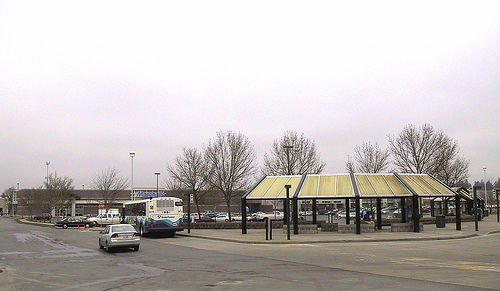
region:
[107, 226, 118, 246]
a tail light on a car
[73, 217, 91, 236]
orange cones in the street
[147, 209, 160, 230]
lights on the back of the bus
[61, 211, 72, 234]
a tire on the car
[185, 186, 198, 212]
a sign on a pole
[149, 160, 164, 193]
a light beside the street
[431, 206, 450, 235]
a garbage can on the sidewalk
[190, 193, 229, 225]
cars parked in the parking lot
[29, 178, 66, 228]
trees planted next to the building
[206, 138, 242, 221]
a tree with no leaves on it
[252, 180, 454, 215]
gold roof on right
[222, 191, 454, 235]
black poles are supporting roof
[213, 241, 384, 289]
sidewalk is dark grey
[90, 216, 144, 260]
silver car on road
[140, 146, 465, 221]
bare trees behind building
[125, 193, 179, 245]
blue and white bus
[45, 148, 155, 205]
tall white light posts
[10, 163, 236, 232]
grey and blue building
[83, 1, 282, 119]
sky is dark and cloudy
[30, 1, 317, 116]
thick white clouds in sky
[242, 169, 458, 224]
gold roof on building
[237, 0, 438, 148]
sky is grey and cloudy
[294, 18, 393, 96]
heavy clouds in sky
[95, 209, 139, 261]
grey car on road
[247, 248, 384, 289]
road is dark grey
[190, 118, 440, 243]
tall trees behind structure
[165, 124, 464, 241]
tall trees are bare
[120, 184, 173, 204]
blue logo on building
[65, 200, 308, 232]
many cars in parking lot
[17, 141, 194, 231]
tall white light poles